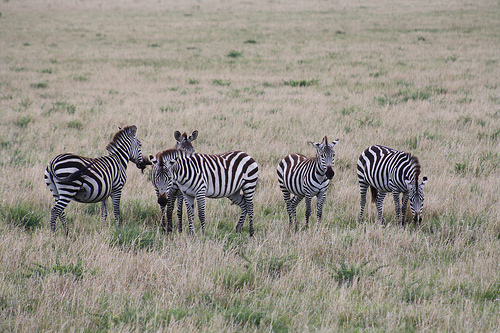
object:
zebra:
[41, 124, 148, 239]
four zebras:
[146, 128, 430, 238]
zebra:
[145, 149, 260, 238]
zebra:
[157, 128, 201, 236]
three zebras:
[39, 123, 261, 238]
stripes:
[246, 165, 259, 177]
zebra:
[275, 135, 344, 234]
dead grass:
[374, 229, 403, 258]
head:
[308, 134, 341, 180]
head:
[147, 153, 180, 207]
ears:
[173, 130, 184, 142]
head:
[173, 129, 200, 154]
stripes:
[168, 160, 175, 166]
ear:
[165, 156, 179, 168]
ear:
[147, 153, 160, 167]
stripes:
[151, 159, 158, 165]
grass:
[0, 1, 499, 331]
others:
[38, 123, 432, 241]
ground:
[0, 0, 500, 333]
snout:
[324, 166, 336, 181]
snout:
[412, 212, 423, 228]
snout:
[157, 191, 168, 207]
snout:
[138, 155, 146, 169]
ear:
[418, 175, 429, 190]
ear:
[402, 176, 414, 194]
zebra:
[355, 143, 429, 230]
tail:
[49, 157, 107, 186]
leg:
[175, 196, 183, 236]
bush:
[322, 251, 392, 293]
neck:
[404, 172, 422, 192]